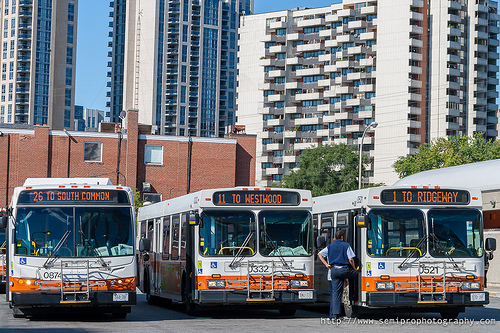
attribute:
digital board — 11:
[220, 167, 306, 201]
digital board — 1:
[376, 190, 464, 209]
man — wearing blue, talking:
[320, 219, 360, 305]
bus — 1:
[299, 184, 488, 325]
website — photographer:
[326, 305, 499, 324]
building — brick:
[9, 112, 259, 196]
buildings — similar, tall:
[13, 5, 233, 133]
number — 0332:
[247, 259, 275, 275]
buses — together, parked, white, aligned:
[11, 152, 499, 319]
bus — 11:
[136, 186, 316, 305]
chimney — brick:
[108, 108, 156, 144]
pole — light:
[349, 122, 382, 196]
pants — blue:
[330, 263, 359, 312]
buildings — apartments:
[249, 7, 490, 204]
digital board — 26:
[26, 189, 116, 201]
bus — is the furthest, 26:
[8, 177, 135, 311]